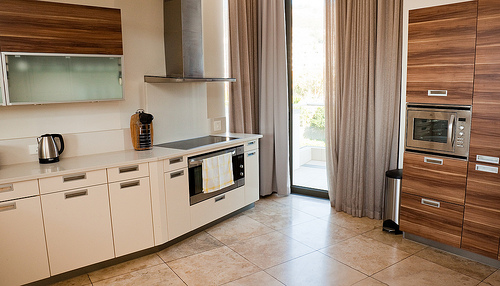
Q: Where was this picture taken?
A: In a kitchen.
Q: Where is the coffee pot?
A: On the countertop.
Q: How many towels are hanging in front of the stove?
A: Two.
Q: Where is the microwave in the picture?
A: On the right.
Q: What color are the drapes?
A: Taupe.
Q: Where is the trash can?
A: To the right of the window.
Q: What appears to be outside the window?
A: A patio.